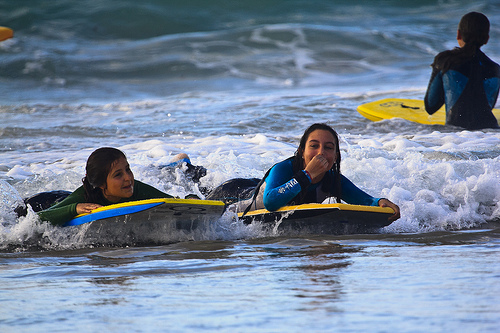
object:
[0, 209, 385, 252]
splash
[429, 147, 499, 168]
ripples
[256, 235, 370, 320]
reflection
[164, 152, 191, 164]
foot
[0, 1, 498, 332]
water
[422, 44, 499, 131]
costume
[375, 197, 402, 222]
hand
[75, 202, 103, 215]
hand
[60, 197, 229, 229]
board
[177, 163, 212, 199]
leg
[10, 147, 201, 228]
ladies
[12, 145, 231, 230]
surfing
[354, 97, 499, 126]
surf board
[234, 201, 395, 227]
surf board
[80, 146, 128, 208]
hair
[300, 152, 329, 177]
lifted hand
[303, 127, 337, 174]
face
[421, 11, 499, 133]
person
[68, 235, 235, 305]
reflection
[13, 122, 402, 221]
these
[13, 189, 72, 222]
wet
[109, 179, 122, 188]
color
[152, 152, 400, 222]
body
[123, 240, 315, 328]
part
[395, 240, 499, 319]
part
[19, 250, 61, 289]
part